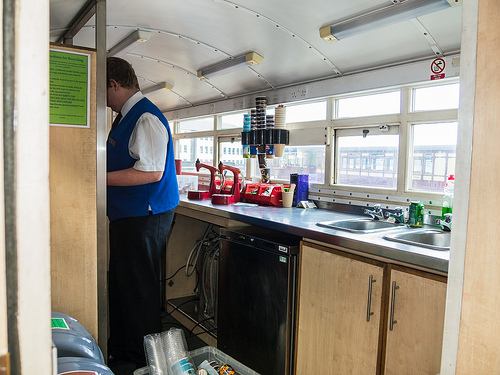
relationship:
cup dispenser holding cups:
[237, 128, 292, 147] [272, 96, 289, 159]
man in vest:
[104, 53, 180, 368] [112, 99, 178, 210]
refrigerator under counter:
[213, 228, 290, 373] [203, 177, 446, 269]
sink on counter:
[388, 227, 448, 251] [246, 210, 325, 222]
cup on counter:
[283, 189, 293, 206] [178, 194, 448, 274]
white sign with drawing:
[429, 48, 446, 83] [432, 59, 443, 70]